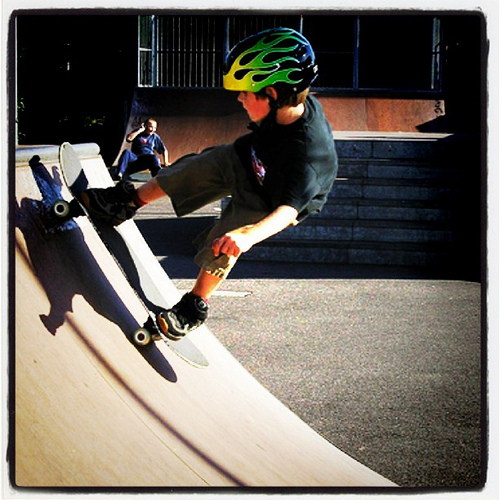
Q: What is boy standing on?
A: Skateboard.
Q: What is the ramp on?
A: Ground.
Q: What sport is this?
A: Skateboard.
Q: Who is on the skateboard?
A: Boy.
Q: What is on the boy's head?
A: Helmet.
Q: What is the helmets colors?
A: Green, yellow and black.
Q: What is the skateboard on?
A: Ramp.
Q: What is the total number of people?
A: 2.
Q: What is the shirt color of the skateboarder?
A: Black.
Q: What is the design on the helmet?
A: Flames.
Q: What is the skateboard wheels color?
A: White.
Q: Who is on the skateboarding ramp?
A: A boy.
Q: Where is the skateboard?
A: On the ramp.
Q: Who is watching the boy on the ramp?
A: A man.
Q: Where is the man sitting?
A: On the floor.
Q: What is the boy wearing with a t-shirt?
A: Tan shorts.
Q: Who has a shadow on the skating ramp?
A: The boy.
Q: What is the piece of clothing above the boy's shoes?
A: Shorts.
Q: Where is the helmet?
A: On the boy's head.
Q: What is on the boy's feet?
A: Shoes.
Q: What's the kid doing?
A: Skateboarding.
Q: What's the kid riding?
A: Skateboard.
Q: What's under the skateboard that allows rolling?
A: Wheels.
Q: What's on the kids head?
A: Helmet.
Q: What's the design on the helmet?
A: Flames.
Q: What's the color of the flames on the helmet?
A: Green and yellow.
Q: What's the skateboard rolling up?
A: Ramp.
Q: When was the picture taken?
A: Daytime.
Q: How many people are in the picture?
A: Two.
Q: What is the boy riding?
A: A skateboard.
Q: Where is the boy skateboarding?
A: On a ramp.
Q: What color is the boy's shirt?
A: Black.